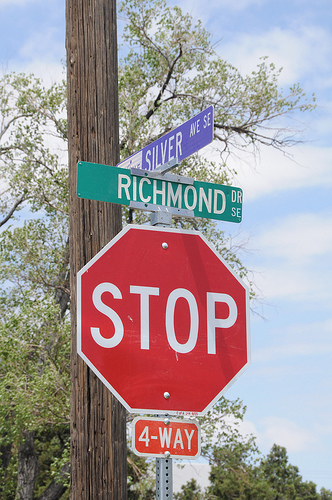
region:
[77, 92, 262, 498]
several signs on a post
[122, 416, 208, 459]
a sign that reads 4-way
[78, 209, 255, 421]
a sign that reads stop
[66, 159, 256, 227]
a green street sign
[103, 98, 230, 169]
a blue street sign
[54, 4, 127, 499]
a telephone pole behind the signs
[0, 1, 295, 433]
green trees in the background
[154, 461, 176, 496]
the post has small holes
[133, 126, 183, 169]
the blue sign says silver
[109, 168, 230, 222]
the green sign says richmond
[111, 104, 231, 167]
blue street sign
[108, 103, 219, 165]
blue street sign reading Silver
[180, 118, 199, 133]
white text on a blue sign reading Ave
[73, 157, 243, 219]
green street sign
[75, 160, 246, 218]
green street sign white text reading Richmond Dr SE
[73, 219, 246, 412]
red stop sign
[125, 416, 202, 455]
red and white 4-Way sign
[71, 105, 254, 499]
four street signs on a metal pole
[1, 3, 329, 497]
lots of trees behind a street signs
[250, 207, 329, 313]
white clouds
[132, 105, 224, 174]
A blue street sign labelled SILVER.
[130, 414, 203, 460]
A red sign labelled 4-WAY.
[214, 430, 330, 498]
Tree Foliage waving in the background.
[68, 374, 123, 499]
A cracked sign post.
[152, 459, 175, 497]
A metal sign post with holes in it.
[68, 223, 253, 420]
A red stop sign.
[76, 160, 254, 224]
A green street sign labelled RICHMOND.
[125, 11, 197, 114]
A thing tree branch with sparse growth.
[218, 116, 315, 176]
The dead and dying limbs of a tree branch.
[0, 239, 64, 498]
A large, healthy tree flanking the stop sign.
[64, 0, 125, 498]
The pole is tall.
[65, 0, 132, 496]
The pole is brown.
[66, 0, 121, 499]
The pole is straight.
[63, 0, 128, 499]
The pole is wood.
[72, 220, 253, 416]
The sign is red.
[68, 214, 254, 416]
The sign is octagonal.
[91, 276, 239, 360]
The letters are white.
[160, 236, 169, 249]
There's a bolt in the sign.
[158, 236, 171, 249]
The bolt is silver.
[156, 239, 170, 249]
The bolt is round.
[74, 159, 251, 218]
green and white street sign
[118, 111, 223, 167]
purple and white street sign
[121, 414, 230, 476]
red and white sign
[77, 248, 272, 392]
red sign with white letters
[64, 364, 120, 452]
holes in utility pole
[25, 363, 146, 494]
green leaves on tree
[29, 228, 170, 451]
tree standing behind pole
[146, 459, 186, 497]
metal post with holes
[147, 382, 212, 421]
metal screw in sign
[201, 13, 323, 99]
blue sky with clouds